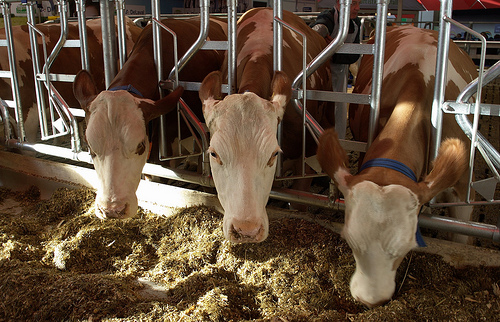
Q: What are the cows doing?
A: Grazing.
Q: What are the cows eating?
A: Hay and grass.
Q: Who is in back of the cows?
A: Farmer.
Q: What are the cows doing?
A: Grazing.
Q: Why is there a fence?
A: To bar the cow.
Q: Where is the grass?
A: On the floor.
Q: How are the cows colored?
A: Brown and white.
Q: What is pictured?
A: Cows.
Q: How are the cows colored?
A: Brown.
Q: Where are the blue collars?
A: Cow's neck.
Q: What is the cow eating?
A: Grass.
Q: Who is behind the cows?
A: A man.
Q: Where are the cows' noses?
A: Near the dirt.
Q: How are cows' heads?
A: White.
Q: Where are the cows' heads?
A: Sticking through the gates.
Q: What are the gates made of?
A: Metal.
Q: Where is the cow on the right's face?
A: In the ground.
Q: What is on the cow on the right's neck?
A: Blue collar.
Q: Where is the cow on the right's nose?
A: In the ground.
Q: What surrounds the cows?
A: Metal bars.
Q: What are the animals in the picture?
A: Cows.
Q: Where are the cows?
A: Cages.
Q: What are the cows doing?
A: Eating.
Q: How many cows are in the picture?
A: Three.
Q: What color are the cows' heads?
A: White.